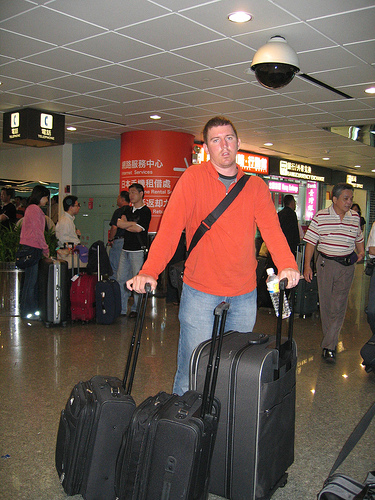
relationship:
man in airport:
[302, 181, 368, 365] [0, 0, 374, 499]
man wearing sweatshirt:
[124, 116, 302, 396] [137, 158, 299, 298]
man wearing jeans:
[124, 116, 302, 396] [172, 282, 258, 396]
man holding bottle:
[124, 116, 302, 396] [265, 267, 290, 320]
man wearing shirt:
[302, 181, 368, 365] [301, 205, 367, 257]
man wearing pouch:
[302, 181, 368, 365] [319, 250, 359, 266]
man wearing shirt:
[116, 183, 152, 317] [116, 203, 152, 252]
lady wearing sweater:
[14, 184, 52, 322] [18, 201, 51, 251]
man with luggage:
[124, 116, 302, 396] [113, 300, 229, 499]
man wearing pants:
[302, 181, 368, 365] [315, 253, 355, 350]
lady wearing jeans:
[14, 184, 52, 322] [19, 245, 40, 317]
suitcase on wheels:
[67, 247, 98, 324] [69, 319, 89, 326]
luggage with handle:
[54, 281, 152, 499] [122, 280, 153, 392]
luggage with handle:
[113, 300, 229, 499] [199, 300, 229, 420]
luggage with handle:
[188, 277, 298, 500] [274, 278, 297, 353]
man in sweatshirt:
[124, 116, 302, 396] [137, 158, 299, 298]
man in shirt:
[302, 181, 368, 365] [301, 205, 367, 257]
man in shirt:
[116, 183, 152, 317] [116, 203, 152, 252]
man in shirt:
[54, 194, 83, 246] [54, 212, 83, 249]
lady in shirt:
[14, 184, 52, 322] [18, 201, 51, 251]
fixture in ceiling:
[227, 10, 253, 24] [0, 1, 374, 179]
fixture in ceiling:
[150, 112, 161, 121] [0, 1, 374, 179]